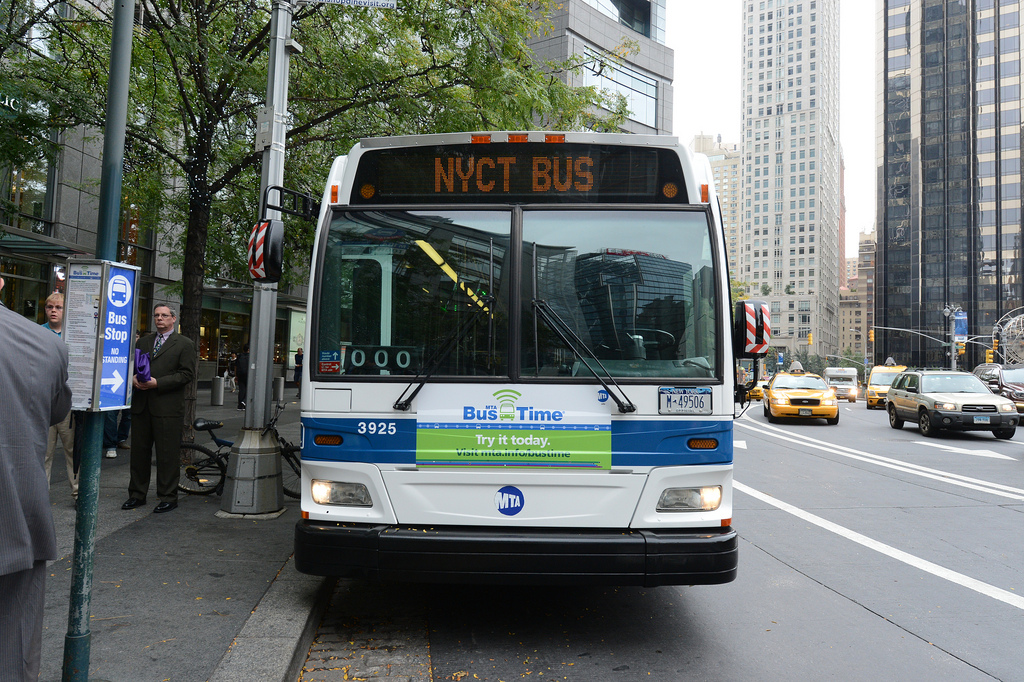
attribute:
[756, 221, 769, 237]
window — glass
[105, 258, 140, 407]
sign — blue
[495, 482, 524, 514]
logo — blue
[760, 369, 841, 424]
taxi — yellow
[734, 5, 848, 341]
building — white, large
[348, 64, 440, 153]
leaves — green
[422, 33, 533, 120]
leaves — green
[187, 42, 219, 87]
leaves — green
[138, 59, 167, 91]
leaves — green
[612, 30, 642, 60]
leaves — green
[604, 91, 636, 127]
leaves — green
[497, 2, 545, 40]
leaves — green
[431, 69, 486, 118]
leaves — green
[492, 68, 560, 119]
leaves — green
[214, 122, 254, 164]
leaves — green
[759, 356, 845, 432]
cab — yellow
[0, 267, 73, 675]
man — light gray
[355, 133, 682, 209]
sign — LED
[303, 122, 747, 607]
bus — blue, white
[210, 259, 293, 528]
pole — metal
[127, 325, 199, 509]
suit — dark gray